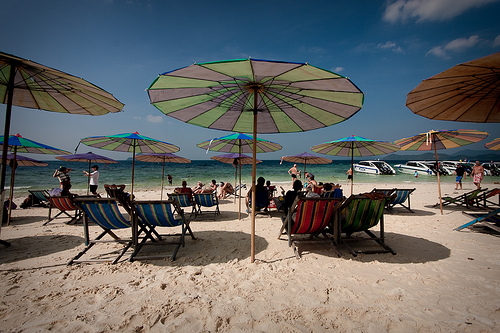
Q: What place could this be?
A: It is a beach.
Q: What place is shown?
A: It is a beach.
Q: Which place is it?
A: It is a beach.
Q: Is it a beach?
A: Yes, it is a beach.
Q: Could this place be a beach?
A: Yes, it is a beach.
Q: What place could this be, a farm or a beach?
A: It is a beach.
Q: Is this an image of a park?
A: No, the picture is showing a beach.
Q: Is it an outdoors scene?
A: Yes, it is outdoors.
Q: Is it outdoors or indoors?
A: It is outdoors.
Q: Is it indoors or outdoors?
A: It is outdoors.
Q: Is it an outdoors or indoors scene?
A: It is outdoors.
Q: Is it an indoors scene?
A: No, it is outdoors.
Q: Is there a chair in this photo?
A: Yes, there is a chair.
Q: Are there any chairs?
A: Yes, there is a chair.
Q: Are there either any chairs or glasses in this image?
A: Yes, there is a chair.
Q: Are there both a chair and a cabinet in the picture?
A: No, there is a chair but no cabinets.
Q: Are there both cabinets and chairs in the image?
A: No, there is a chair but no cabinets.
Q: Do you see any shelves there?
A: No, there are no shelves.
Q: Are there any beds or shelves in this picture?
A: No, there are no shelves or beds.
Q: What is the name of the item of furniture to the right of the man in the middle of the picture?
A: The piece of furniture is a chair.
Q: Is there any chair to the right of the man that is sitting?
A: Yes, there is a chair to the right of the man.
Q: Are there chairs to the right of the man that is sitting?
A: Yes, there is a chair to the right of the man.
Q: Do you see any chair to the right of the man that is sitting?
A: Yes, there is a chair to the right of the man.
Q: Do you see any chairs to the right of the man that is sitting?
A: Yes, there is a chair to the right of the man.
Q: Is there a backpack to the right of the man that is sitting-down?
A: No, there is a chair to the right of the man.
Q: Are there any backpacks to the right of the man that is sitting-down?
A: No, there is a chair to the right of the man.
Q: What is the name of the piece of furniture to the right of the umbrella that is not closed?
A: The piece of furniture is a chair.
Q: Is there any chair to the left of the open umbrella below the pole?
A: No, the chair is to the right of the umbrella.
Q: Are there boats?
A: Yes, there is a boat.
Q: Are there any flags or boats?
A: Yes, there is a boat.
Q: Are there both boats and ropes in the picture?
A: No, there is a boat but no ropes.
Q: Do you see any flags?
A: No, there are no flags.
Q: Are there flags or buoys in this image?
A: No, there are no flags or buoys.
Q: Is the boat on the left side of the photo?
A: No, the boat is on the right of the image.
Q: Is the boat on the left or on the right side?
A: The boat is on the right of the image.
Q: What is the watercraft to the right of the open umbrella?
A: The watercraft is a boat.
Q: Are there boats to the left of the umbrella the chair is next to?
A: No, the boat is to the right of the umbrella.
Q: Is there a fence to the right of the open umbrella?
A: No, there is a boat to the right of the umbrella.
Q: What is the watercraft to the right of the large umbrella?
A: The watercraft is a boat.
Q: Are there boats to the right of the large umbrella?
A: Yes, there is a boat to the right of the umbrella.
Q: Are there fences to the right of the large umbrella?
A: No, there is a boat to the right of the umbrella.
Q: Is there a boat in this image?
A: Yes, there is a boat.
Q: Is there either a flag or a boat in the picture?
A: Yes, there is a boat.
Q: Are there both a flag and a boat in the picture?
A: No, there is a boat but no flags.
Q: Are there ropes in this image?
A: No, there are no ropes.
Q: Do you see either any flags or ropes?
A: No, there are no ropes or flags.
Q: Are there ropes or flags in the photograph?
A: No, there are no ropes or flags.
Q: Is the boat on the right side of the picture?
A: Yes, the boat is on the right of the image.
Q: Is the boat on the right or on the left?
A: The boat is on the right of the image.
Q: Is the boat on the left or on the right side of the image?
A: The boat is on the right of the image.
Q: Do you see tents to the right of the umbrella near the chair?
A: No, there is a boat to the right of the umbrella.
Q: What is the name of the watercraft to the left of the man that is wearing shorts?
A: The watercraft is a boat.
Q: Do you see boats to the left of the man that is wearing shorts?
A: Yes, there is a boat to the left of the man.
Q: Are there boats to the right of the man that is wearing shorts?
A: No, the boat is to the left of the man.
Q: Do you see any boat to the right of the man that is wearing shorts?
A: No, the boat is to the left of the man.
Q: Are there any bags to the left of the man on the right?
A: No, there is a boat to the left of the man.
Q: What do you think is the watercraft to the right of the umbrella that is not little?
A: The watercraft is a boat.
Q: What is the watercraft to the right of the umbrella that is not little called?
A: The watercraft is a boat.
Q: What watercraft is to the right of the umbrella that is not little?
A: The watercraft is a boat.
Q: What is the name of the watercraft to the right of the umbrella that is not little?
A: The watercraft is a boat.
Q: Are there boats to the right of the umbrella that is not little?
A: Yes, there is a boat to the right of the umbrella.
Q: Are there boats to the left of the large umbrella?
A: No, the boat is to the right of the umbrella.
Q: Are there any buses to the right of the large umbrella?
A: No, there is a boat to the right of the umbrella.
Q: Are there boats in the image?
A: Yes, there is a boat.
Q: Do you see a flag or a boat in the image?
A: Yes, there is a boat.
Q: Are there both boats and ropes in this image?
A: No, there is a boat but no ropes.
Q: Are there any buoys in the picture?
A: No, there are no buoys.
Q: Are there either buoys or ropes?
A: No, there are no buoys or ropes.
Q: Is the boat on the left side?
A: No, the boat is on the right of the image.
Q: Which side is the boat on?
A: The boat is on the right of the image.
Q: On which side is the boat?
A: The boat is on the right of the image.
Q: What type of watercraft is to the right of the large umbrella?
A: The watercraft is a boat.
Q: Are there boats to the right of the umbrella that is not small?
A: Yes, there is a boat to the right of the umbrella.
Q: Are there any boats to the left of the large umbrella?
A: No, the boat is to the right of the umbrella.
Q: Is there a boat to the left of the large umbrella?
A: No, the boat is to the right of the umbrella.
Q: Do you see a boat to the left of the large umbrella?
A: No, the boat is to the right of the umbrella.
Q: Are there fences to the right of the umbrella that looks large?
A: No, there is a boat to the right of the umbrella.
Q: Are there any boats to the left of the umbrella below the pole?
A: No, the boat is to the right of the umbrella.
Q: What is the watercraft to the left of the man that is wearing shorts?
A: The watercraft is a boat.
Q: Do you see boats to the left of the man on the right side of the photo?
A: Yes, there is a boat to the left of the man.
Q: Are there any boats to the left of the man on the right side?
A: Yes, there is a boat to the left of the man.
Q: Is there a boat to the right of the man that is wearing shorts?
A: No, the boat is to the left of the man.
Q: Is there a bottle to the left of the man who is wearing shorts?
A: No, there is a boat to the left of the man.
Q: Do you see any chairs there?
A: Yes, there is a chair.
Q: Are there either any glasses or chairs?
A: Yes, there is a chair.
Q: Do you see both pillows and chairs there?
A: No, there is a chair but no pillows.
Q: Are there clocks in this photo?
A: No, there are no clocks.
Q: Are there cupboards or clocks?
A: No, there are no clocks or cupboards.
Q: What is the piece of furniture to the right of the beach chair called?
A: The piece of furniture is a chair.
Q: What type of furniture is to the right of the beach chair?
A: The piece of furniture is a chair.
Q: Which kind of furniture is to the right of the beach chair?
A: The piece of furniture is a chair.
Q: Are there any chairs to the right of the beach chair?
A: Yes, there is a chair to the right of the beach chair.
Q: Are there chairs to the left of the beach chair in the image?
A: No, the chair is to the right of the beach chair.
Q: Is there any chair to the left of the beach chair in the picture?
A: No, the chair is to the right of the beach chair.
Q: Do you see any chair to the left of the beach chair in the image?
A: No, the chair is to the right of the beach chair.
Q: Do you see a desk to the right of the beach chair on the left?
A: No, there is a chair to the right of the beach chair.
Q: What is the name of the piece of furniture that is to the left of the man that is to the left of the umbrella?
A: The piece of furniture is a chair.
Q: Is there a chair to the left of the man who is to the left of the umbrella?
A: Yes, there is a chair to the left of the man.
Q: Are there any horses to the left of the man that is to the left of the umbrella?
A: No, there is a chair to the left of the man.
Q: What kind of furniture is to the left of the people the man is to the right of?
A: The piece of furniture is a chair.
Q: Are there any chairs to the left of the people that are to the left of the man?
A: Yes, there is a chair to the left of the people.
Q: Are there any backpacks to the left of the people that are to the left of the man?
A: No, there is a chair to the left of the people.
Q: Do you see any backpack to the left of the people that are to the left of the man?
A: No, there is a chair to the left of the people.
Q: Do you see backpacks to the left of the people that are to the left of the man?
A: No, there is a chair to the left of the people.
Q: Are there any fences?
A: No, there are no fences.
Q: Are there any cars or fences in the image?
A: No, there are no fences or cars.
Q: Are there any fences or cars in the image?
A: No, there are no fences or cars.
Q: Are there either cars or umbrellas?
A: Yes, there is an umbrella.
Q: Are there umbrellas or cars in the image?
A: Yes, there is an umbrella.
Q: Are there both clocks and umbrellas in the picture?
A: No, there is an umbrella but no clocks.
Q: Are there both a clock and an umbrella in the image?
A: No, there is an umbrella but no clocks.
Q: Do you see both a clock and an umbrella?
A: No, there is an umbrella but no clocks.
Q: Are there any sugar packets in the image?
A: No, there are no sugar packets.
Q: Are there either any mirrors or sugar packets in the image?
A: No, there are no sugar packets or mirrors.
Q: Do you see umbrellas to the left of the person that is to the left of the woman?
A: Yes, there is an umbrella to the left of the person.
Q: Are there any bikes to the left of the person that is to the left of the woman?
A: No, there is an umbrella to the left of the person.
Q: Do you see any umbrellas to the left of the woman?
A: Yes, there is an umbrella to the left of the woman.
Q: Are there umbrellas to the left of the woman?
A: Yes, there is an umbrella to the left of the woman.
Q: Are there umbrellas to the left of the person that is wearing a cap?
A: Yes, there is an umbrella to the left of the woman.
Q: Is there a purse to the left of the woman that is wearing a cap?
A: No, there is an umbrella to the left of the woman.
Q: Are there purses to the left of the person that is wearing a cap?
A: No, there is an umbrella to the left of the woman.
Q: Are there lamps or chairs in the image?
A: Yes, there is a chair.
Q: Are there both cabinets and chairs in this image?
A: No, there is a chair but no cabinets.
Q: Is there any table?
A: No, there are no tables.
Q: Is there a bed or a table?
A: No, there are no tables or beds.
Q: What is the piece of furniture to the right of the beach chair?
A: The piece of furniture is a chair.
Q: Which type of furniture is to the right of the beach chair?
A: The piece of furniture is a chair.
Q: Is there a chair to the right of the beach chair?
A: Yes, there is a chair to the right of the beach chair.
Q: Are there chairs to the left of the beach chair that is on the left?
A: No, the chair is to the right of the beach chair.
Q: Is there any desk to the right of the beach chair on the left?
A: No, there is a chair to the right of the beach chair.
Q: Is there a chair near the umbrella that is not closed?
A: Yes, there is a chair near the umbrella.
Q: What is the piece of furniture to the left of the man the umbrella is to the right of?
A: The piece of furniture is a chair.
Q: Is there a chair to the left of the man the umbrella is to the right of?
A: Yes, there is a chair to the left of the man.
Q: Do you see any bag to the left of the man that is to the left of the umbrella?
A: No, there is a chair to the left of the man.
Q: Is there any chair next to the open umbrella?
A: Yes, there is a chair next to the umbrella.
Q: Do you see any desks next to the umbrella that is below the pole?
A: No, there is a chair next to the umbrella.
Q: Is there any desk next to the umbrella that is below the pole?
A: No, there is a chair next to the umbrella.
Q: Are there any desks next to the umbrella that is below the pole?
A: No, there is a chair next to the umbrella.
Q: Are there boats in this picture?
A: Yes, there is a boat.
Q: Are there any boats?
A: Yes, there is a boat.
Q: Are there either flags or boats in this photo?
A: Yes, there is a boat.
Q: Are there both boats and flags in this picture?
A: No, there is a boat but no flags.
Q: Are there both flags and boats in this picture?
A: No, there is a boat but no flags.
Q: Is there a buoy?
A: No, there are no buoys.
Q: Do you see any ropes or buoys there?
A: No, there are no buoys or ropes.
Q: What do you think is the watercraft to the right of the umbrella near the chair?
A: The watercraft is a boat.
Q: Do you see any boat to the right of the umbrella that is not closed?
A: Yes, there is a boat to the right of the umbrella.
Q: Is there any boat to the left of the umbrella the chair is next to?
A: No, the boat is to the right of the umbrella.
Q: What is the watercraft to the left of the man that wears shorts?
A: The watercraft is a boat.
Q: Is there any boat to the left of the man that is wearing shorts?
A: Yes, there is a boat to the left of the man.